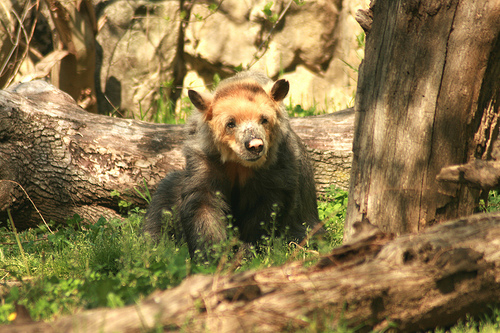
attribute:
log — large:
[3, 85, 363, 226]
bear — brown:
[135, 77, 332, 275]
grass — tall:
[4, 190, 347, 315]